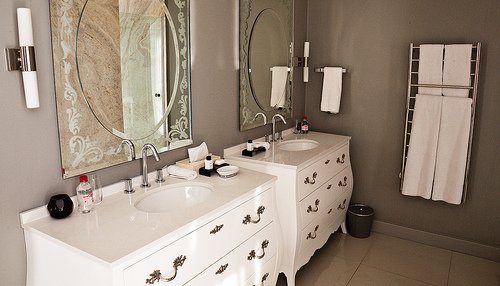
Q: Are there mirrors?
A: Yes, there is a mirror.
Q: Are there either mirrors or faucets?
A: Yes, there is a mirror.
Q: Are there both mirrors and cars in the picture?
A: No, there is a mirror but no cars.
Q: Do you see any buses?
A: No, there are no buses.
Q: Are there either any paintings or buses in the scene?
A: No, there are no buses or paintings.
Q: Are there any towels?
A: Yes, there is a towel.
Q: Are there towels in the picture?
A: Yes, there is a towel.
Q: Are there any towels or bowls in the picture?
A: Yes, there is a towel.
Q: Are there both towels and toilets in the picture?
A: No, there is a towel but no toilets.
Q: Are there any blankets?
A: No, there are no blankets.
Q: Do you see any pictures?
A: No, there are no pictures.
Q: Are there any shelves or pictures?
A: No, there are no pictures or shelves.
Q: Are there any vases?
A: No, there are no vases.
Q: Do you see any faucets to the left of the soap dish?
A: Yes, there is a faucet to the left of the soap dish.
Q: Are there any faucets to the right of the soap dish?
A: No, the faucet is to the left of the soap dish.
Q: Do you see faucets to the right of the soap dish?
A: No, the faucet is to the left of the soap dish.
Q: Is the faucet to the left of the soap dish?
A: Yes, the faucet is to the left of the soap dish.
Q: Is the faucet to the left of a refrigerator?
A: No, the faucet is to the left of the soap dish.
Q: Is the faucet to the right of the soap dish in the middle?
A: No, the faucet is to the left of the soap dish.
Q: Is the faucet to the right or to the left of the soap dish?
A: The faucet is to the left of the soap dish.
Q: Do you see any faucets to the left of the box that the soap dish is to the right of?
A: Yes, there is a faucet to the left of the box.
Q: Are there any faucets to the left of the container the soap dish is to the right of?
A: Yes, there is a faucet to the left of the box.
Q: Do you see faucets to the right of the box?
A: No, the faucet is to the left of the box.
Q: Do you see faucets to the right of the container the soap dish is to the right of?
A: No, the faucet is to the left of the box.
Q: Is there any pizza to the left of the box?
A: No, there is a faucet to the left of the box.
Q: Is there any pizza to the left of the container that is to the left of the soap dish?
A: No, there is a faucet to the left of the box.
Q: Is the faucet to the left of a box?
A: Yes, the faucet is to the left of a box.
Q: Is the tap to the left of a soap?
A: No, the tap is to the left of a box.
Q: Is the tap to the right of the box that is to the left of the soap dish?
A: No, the tap is to the left of the box.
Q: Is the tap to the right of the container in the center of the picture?
A: No, the tap is to the left of the box.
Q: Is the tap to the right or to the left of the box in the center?
A: The tap is to the left of the box.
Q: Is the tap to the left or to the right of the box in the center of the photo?
A: The tap is to the left of the box.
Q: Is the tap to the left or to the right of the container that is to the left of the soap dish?
A: The tap is to the left of the box.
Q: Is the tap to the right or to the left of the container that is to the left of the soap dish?
A: The tap is to the left of the box.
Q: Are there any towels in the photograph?
A: Yes, there is a towel.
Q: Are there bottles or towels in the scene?
A: Yes, there is a towel.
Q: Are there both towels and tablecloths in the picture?
A: No, there is a towel but no tablecloths.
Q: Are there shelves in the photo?
A: No, there are no shelves.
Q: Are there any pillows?
A: No, there are no pillows.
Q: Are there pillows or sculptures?
A: No, there are no pillows or sculptures.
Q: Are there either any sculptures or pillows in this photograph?
A: No, there are no pillows or sculptures.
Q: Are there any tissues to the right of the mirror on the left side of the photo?
A: Yes, there are tissues to the right of the mirror.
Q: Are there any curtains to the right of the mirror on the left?
A: No, there are tissues to the right of the mirror.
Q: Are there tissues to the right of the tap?
A: Yes, there are tissues to the right of the tap.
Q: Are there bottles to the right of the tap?
A: No, there are tissues to the right of the tap.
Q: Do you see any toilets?
A: No, there are no toilets.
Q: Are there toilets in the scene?
A: No, there are no toilets.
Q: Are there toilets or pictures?
A: No, there are no toilets or pictures.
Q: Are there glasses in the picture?
A: No, there are no glasses.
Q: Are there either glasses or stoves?
A: No, there are no glasses or stoves.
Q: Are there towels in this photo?
A: Yes, there is a towel.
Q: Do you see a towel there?
A: Yes, there is a towel.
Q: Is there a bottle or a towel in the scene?
A: Yes, there is a towel.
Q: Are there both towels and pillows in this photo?
A: No, there is a towel but no pillows.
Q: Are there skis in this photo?
A: No, there are no skis.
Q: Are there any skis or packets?
A: No, there are no skis or packets.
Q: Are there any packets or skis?
A: No, there are no skis or packets.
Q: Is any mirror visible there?
A: Yes, there is a mirror.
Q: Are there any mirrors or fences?
A: Yes, there is a mirror.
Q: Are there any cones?
A: No, there are no cones.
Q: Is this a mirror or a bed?
A: This is a mirror.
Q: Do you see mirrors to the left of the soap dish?
A: Yes, there is a mirror to the left of the soap dish.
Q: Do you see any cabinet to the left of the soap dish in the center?
A: No, there is a mirror to the left of the soap dish.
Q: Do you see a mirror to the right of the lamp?
A: Yes, there is a mirror to the right of the lamp.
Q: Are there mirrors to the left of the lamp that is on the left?
A: No, the mirror is to the right of the lamp.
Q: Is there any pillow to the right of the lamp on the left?
A: No, there is a mirror to the right of the lamp.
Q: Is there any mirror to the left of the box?
A: Yes, there is a mirror to the left of the box.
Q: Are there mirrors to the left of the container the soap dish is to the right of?
A: Yes, there is a mirror to the left of the box.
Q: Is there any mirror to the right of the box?
A: No, the mirror is to the left of the box.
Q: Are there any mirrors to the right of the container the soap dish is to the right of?
A: No, the mirror is to the left of the box.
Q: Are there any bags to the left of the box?
A: No, there is a mirror to the left of the box.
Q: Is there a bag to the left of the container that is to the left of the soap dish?
A: No, there is a mirror to the left of the box.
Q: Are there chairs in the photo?
A: No, there are no chairs.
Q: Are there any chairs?
A: No, there are no chairs.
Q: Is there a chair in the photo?
A: No, there are no chairs.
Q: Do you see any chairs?
A: No, there are no chairs.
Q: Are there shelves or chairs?
A: No, there are no chairs or shelves.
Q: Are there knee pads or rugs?
A: No, there are no rugs or knee pads.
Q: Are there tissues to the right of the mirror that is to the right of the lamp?
A: Yes, there are tissues to the right of the mirror.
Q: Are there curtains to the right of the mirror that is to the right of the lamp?
A: No, there are tissues to the right of the mirror.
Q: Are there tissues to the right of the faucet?
A: Yes, there are tissues to the right of the faucet.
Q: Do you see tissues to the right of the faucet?
A: Yes, there are tissues to the right of the faucet.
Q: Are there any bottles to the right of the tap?
A: No, there are tissues to the right of the tap.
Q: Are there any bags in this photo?
A: No, there are no bags.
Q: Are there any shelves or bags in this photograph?
A: No, there are no bags or shelves.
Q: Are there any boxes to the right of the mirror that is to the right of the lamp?
A: Yes, there is a box to the right of the mirror.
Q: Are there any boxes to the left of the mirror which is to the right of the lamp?
A: No, the box is to the right of the mirror.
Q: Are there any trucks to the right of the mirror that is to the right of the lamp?
A: No, there is a box to the right of the mirror.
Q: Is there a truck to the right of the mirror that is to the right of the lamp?
A: No, there is a box to the right of the mirror.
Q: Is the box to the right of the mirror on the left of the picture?
A: Yes, the box is to the right of the mirror.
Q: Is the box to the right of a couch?
A: No, the box is to the right of the mirror.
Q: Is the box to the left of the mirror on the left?
A: No, the box is to the right of the mirror.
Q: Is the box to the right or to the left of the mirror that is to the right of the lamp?
A: The box is to the right of the mirror.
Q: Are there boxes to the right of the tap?
A: Yes, there is a box to the right of the tap.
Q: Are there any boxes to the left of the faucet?
A: No, the box is to the right of the faucet.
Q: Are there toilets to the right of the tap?
A: No, there is a box to the right of the tap.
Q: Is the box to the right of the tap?
A: Yes, the box is to the right of the tap.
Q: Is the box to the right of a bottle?
A: No, the box is to the right of the tap.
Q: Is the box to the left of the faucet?
A: No, the box is to the right of the faucet.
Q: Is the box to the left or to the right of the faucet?
A: The box is to the right of the faucet.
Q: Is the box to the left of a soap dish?
A: Yes, the box is to the left of a soap dish.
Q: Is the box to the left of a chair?
A: No, the box is to the left of a soap dish.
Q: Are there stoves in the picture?
A: No, there are no stoves.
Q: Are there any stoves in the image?
A: No, there are no stoves.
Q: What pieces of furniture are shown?
A: The pieces of furniture are drawers.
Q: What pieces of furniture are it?
A: The pieces of furniture are drawers.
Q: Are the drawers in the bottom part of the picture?
A: Yes, the drawers are in the bottom of the image.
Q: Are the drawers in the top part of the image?
A: No, the drawers are in the bottom of the image.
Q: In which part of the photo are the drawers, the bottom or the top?
A: The drawers are in the bottom of the image.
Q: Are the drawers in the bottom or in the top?
A: The drawers are in the bottom of the image.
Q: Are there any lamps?
A: Yes, there is a lamp.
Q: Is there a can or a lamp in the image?
A: Yes, there is a lamp.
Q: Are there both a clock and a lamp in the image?
A: No, there is a lamp but no clocks.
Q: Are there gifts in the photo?
A: No, there are no gifts.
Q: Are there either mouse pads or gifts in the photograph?
A: No, there are no gifts or mouse pads.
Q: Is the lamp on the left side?
A: Yes, the lamp is on the left of the image.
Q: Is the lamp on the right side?
A: No, the lamp is on the left of the image.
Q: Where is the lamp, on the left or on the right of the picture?
A: The lamp is on the left of the image.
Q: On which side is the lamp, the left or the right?
A: The lamp is on the left of the image.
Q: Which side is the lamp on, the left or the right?
A: The lamp is on the left of the image.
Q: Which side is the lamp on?
A: The lamp is on the left of the image.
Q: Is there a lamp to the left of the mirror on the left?
A: Yes, there is a lamp to the left of the mirror.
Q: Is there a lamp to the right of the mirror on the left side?
A: No, the lamp is to the left of the mirror.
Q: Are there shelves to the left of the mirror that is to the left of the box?
A: No, there is a lamp to the left of the mirror.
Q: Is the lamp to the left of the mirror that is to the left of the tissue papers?
A: Yes, the lamp is to the left of the mirror.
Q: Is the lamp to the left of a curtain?
A: No, the lamp is to the left of the mirror.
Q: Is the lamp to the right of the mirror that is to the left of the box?
A: No, the lamp is to the left of the mirror.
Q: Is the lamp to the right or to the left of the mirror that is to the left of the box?
A: The lamp is to the left of the mirror.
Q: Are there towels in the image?
A: Yes, there is a towel.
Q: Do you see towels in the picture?
A: Yes, there is a towel.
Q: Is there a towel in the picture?
A: Yes, there is a towel.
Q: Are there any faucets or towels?
A: Yes, there is a towel.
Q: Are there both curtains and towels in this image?
A: No, there is a towel but no curtains.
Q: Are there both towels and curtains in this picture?
A: No, there is a towel but no curtains.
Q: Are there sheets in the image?
A: No, there are no sheets.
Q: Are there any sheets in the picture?
A: No, there are no sheets.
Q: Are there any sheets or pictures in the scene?
A: No, there are no sheets or pictures.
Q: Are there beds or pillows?
A: No, there are no pillows or beds.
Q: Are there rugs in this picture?
A: No, there are no rugs.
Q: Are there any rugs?
A: No, there are no rugs.